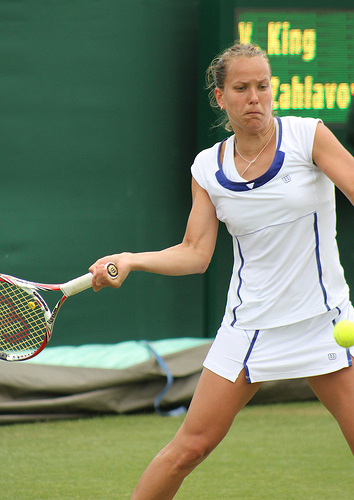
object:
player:
[87, 44, 351, 499]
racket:
[1, 258, 119, 365]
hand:
[88, 252, 133, 291]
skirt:
[200, 296, 349, 384]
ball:
[331, 318, 353, 348]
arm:
[122, 161, 218, 277]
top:
[191, 116, 351, 334]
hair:
[203, 43, 270, 135]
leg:
[131, 364, 262, 499]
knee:
[163, 437, 213, 471]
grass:
[1, 400, 352, 499]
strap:
[134, 339, 186, 419]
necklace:
[231, 128, 278, 179]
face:
[223, 55, 271, 131]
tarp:
[1, 338, 317, 423]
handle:
[58, 262, 121, 300]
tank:
[222, 133, 251, 184]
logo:
[327, 349, 339, 361]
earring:
[218, 102, 226, 111]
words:
[238, 20, 354, 113]